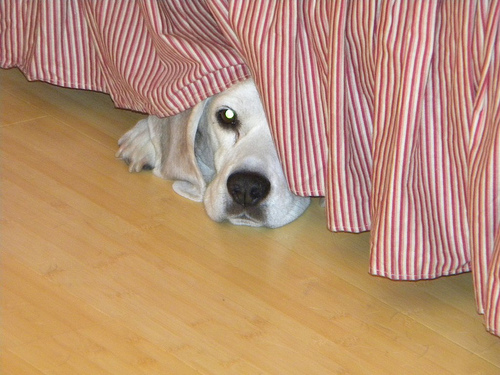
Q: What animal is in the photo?
A: Dog.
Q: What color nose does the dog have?
A: Black.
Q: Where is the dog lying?
A: The floor.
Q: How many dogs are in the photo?
A: One.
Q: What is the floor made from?
A: Wood.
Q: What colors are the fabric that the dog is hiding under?
A: Red, White.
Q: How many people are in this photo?
A: Zero.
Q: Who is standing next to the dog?
A: No one.